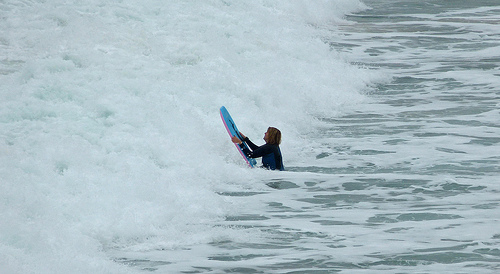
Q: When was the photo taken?
A: Daytime.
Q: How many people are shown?
A: One.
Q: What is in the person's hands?
A: Surf board.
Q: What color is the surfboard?
A: Blue.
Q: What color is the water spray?
A: White.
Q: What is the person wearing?
A: Wet suit.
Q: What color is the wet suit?
A: Blue and black.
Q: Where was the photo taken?
A: At the ocean.